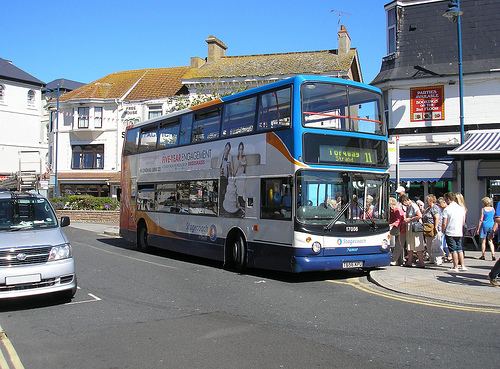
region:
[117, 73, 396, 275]
a double-decker bus parked on the street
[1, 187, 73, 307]
a gray minivan parked on the street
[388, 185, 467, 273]
people waiting to embark a bus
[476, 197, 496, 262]
a blonde woman wearing a blue dress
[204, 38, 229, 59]
a stone chimney on top of a house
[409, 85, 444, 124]
a red advertisement on the white wall of a building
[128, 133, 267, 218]
an advertisement on the side of a double-decker bus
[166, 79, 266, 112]
ivy on the wall of a house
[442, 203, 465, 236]
man wearing a white shirt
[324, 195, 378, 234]
wipers on a bus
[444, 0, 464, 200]
the light post on the sidewalk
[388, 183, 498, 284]
the people in the sidewalk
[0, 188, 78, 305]
the parked vehicle on the road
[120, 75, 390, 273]
the double decker bus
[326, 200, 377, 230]
the windshield wipers on the bus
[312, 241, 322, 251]
the light on the bus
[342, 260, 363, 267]
the license plate on the bus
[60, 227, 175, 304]
the white lines on the road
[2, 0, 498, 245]
the buildings in the area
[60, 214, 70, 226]
the driver's side view mirror on the vehicle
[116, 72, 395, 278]
Bus parked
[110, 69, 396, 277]
Bus is parked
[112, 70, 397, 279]
Double decker bus parked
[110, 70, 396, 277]
Double decker bus is parked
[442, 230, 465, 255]
Man is wearing blue denim shorts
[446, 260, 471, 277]
Man is wearing white shoes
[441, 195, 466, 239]
Man is wearing a white shirt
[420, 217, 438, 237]
Woman is carrying a brown purse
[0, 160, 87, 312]
Car is parked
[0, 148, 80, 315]
White car is parked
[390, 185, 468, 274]
people at a bus stop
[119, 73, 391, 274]
bus has two levels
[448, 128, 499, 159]
building with white and blue awning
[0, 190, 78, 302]
car parked on street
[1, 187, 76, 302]
gray car on street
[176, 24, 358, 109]
chimney on top of house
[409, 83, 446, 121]
red sign on building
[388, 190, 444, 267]
three women carrying bags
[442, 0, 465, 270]
light post in front of building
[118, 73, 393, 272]
bus stopped at bus stop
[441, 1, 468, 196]
a large blue light pole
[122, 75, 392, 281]
a large blue and white bus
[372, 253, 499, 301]
part of a sidewalk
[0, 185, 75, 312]
part of a gray van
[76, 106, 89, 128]
a window of a building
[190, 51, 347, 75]
a roof of a building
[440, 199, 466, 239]
a man's white shirt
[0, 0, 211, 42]
part of a blue sky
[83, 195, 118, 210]
a large green bush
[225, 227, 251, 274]
a black bus tire